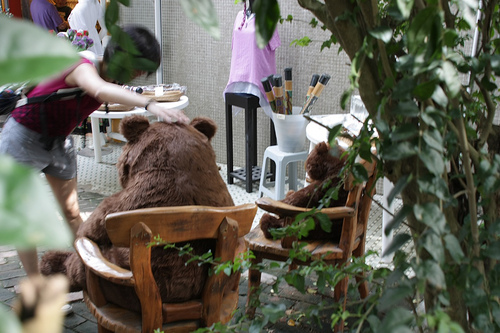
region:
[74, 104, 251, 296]
this is a teddy bear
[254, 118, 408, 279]
this is a teddy bear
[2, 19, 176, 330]
this is a person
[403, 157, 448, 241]
leaves on a tree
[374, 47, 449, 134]
leaves on a tree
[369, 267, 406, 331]
leaves on a tree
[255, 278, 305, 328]
leaves on a tree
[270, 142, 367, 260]
A brown bear on a seat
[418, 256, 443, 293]
A green tree leaf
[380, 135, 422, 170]
A green tree leaf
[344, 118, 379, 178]
A green tree leaf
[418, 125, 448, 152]
A green tree leaf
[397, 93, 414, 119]
A green tree leaf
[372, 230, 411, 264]
A green tree leaf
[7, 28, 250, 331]
woman with her hand on a bear in a chair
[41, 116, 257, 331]
large bear in left chair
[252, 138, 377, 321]
small bear in right chair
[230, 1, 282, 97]
pink shirt on mannequin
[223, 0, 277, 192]
small black table with a mannequin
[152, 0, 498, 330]
green tree in foreground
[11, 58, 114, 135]
woman's pink shirt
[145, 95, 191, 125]
woman's hand on bear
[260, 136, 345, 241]
a little brown stuffed bear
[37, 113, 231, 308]
a big stuffed brown bear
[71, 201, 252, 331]
The wooden chair the large bear is sitting in.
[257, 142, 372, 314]
The wooden chair the small bear is sitting in.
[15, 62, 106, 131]
The red shirt the lady is wearing.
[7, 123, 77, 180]
The gray shorts the lady is wearing.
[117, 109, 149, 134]
The left ear of the large bear.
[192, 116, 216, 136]
The right ear of the large bear.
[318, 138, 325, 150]
The left ear of the small bear.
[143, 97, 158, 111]
The black bracelet the woman has on her wrist.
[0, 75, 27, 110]
The bag the lady is carrying.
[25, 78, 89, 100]
The strap of the bag the lady is carrying.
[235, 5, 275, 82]
The purple shirt on the stool.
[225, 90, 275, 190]
The black stool.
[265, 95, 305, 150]
The white pail.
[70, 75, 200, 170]
The white table.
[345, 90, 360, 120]
The glass on the table on the right.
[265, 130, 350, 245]
The bear on the chair on the right.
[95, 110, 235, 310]
The large bear on the chair.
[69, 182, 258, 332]
The wooden chair the large bear is sitting on.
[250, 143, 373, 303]
The wooden chair the small bear is sitting on.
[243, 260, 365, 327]
The legs of the chair the small bear is sitting on.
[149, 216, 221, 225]
back of the chair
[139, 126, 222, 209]
bear in the chair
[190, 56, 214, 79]
the wall is brick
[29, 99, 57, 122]
the tank is red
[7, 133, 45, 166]
the shorts are denim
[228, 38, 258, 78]
the shirt is pink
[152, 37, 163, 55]
the hair is black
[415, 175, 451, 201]
green leaf on the tree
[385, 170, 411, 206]
green leaf on the tree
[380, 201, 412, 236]
green leaf on the tree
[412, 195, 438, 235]
green leaf on the tree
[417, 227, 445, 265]
green leaf on the tree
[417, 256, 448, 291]
green leaf on the tree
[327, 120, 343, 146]
green leaf on the tree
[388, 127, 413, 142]
green leaf on the tree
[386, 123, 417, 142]
green leaf on the tree